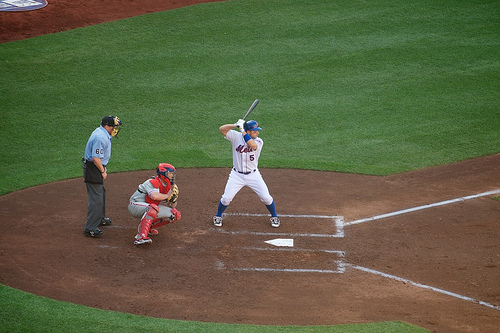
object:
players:
[213, 119, 281, 228]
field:
[1, 0, 498, 332]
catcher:
[128, 163, 182, 246]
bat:
[236, 99, 260, 126]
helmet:
[243, 120, 262, 130]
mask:
[162, 164, 175, 183]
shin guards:
[135, 203, 159, 239]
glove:
[168, 184, 179, 202]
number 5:
[250, 154, 255, 161]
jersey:
[223, 130, 263, 173]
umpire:
[80, 113, 123, 239]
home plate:
[264, 237, 295, 250]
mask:
[112, 115, 122, 137]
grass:
[2, 1, 498, 331]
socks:
[265, 201, 278, 216]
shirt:
[81, 125, 112, 167]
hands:
[235, 119, 245, 132]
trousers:
[219, 168, 274, 206]